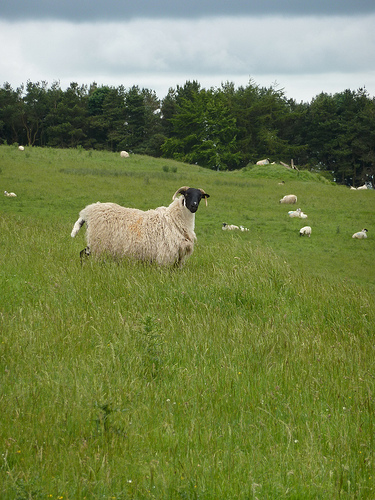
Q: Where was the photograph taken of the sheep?
A: Pasture.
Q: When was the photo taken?
A: Daytime.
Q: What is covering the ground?
A: Grass.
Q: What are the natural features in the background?
A: Trees.